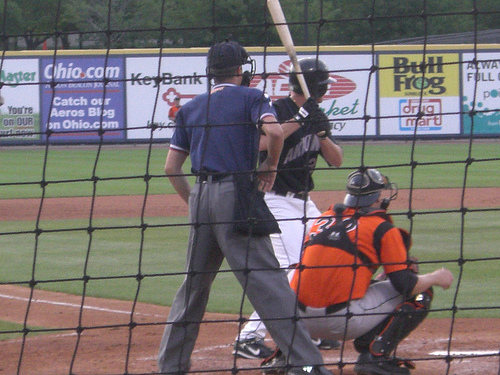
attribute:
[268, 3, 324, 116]
bat — wooden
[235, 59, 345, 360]
player — batting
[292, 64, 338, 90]
helmet — black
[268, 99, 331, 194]
jersey — black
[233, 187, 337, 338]
pants — white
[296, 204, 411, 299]
jersey — orange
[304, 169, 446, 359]
catcher — squatting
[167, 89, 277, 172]
shirt — blue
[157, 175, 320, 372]
pants — gray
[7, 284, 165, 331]
line — white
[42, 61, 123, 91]
sponsor — blue, white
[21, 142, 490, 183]
grass — green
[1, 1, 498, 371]
net — black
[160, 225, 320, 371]
legs — spread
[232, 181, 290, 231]
bag — black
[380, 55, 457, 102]
advertising — yellow